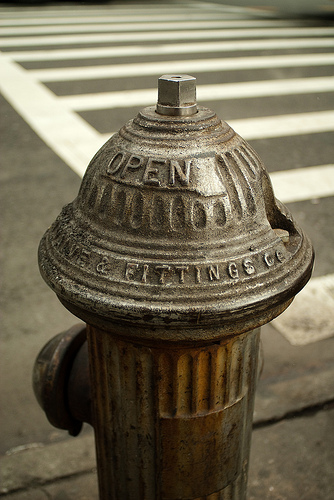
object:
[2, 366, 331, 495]
curb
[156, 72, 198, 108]
nut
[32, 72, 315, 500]
fire hydrant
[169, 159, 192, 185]
word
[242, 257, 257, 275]
word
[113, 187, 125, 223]
indentation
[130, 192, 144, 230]
indentation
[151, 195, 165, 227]
indentation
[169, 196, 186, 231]
indentation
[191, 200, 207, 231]
indentation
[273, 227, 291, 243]
bolt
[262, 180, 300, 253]
opening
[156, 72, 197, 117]
angle bolt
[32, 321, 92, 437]
nozzle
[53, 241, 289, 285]
company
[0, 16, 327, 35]
lines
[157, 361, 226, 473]
rust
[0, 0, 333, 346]
cross walk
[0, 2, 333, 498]
paved street